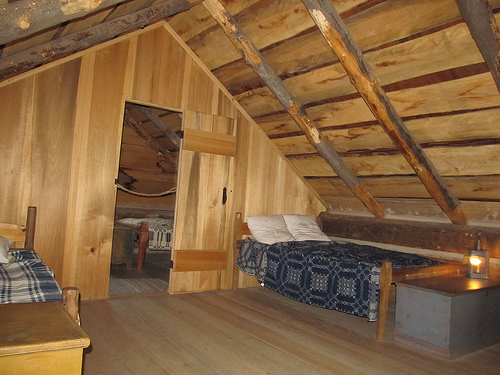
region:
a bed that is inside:
[214, 172, 484, 370]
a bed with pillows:
[212, 203, 455, 364]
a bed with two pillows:
[252, 179, 416, 360]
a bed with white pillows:
[237, 194, 419, 334]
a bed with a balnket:
[211, 206, 436, 336]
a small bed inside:
[234, 186, 446, 367]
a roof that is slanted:
[161, 8, 499, 256]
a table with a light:
[377, 228, 498, 316]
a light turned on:
[422, 221, 496, 322]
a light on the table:
[422, 229, 496, 321]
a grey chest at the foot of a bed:
[390, 272, 497, 357]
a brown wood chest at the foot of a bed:
[0, 301, 88, 371]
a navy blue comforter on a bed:
[238, 239, 446, 324]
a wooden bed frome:
[229, 210, 473, 337]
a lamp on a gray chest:
[462, 234, 492, 283]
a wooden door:
[167, 115, 238, 295]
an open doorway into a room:
[107, 98, 182, 300]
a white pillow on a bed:
[246, 212, 294, 244]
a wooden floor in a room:
[74, 284, 498, 374]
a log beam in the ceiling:
[204, 0, 385, 218]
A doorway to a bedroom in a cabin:
[107, 95, 182, 292]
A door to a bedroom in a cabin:
[169, 111, 239, 296]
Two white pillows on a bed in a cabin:
[246, 215, 331, 245]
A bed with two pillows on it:
[235, 230, 455, 322]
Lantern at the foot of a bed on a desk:
[464, 234, 489, 278]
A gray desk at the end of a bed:
[397, 269, 499, 362]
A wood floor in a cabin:
[75, 290, 497, 372]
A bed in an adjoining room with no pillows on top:
[117, 215, 172, 273]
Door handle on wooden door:
[221, 185, 227, 206]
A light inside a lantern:
[467, 256, 483, 263]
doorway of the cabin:
[100, 98, 180, 298]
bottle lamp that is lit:
[464, 233, 493, 282]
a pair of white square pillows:
[246, 211, 332, 246]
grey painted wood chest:
[392, 268, 497, 361]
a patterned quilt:
[240, 232, 445, 323]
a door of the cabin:
[167, 110, 241, 300]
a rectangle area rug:
[107, 280, 168, 299]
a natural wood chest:
[0, 298, 94, 374]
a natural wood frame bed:
[235, 210, 468, 340]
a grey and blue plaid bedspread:
[0, 245, 70, 306]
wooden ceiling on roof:
[339, 15, 470, 93]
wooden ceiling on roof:
[280, 54, 359, 101]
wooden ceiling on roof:
[324, 118, 386, 156]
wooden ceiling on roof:
[269, 138, 315, 160]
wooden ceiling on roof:
[212, 51, 262, 92]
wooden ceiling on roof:
[197, 23, 261, 64]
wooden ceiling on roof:
[322, 195, 379, 212]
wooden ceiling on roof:
[375, 189, 442, 222]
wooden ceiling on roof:
[367, 168, 434, 200]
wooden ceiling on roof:
[444, 171, 496, 201]